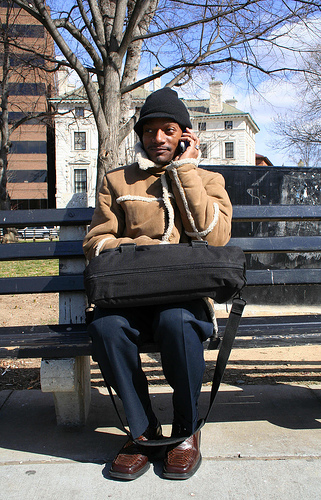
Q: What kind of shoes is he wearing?
A: Loafers.